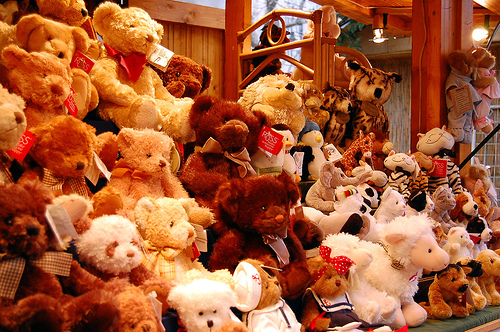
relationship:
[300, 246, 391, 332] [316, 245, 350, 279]
bear has bow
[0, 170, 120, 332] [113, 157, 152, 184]
bear wearing brown bow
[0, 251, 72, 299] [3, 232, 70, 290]
bow around neck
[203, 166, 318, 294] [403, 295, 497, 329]
bear on table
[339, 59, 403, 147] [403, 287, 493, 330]
bear on table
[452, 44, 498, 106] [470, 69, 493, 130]
bear has outfit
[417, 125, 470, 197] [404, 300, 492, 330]
animal on table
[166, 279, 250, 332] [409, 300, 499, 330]
animal on table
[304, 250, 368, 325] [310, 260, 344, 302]
bear has head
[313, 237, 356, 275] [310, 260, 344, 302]
bow on head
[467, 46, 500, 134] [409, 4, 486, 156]
bear hanging from wall